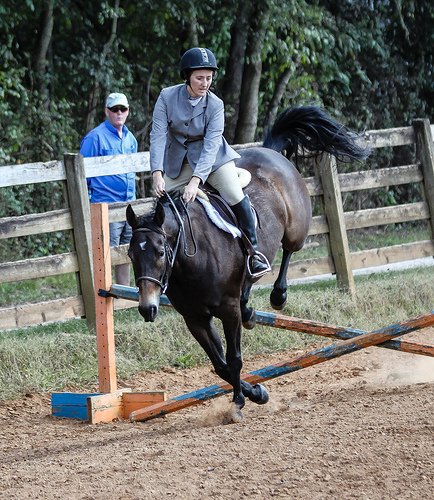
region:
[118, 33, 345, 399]
A woman riding a black horse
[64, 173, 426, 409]
Horse jumping fences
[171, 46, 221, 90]
A black riders hat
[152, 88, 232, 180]
A woman wearing a light gray jacket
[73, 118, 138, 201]
A blue long sleeved shirt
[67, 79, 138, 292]
A man standing on other side of fence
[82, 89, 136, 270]
A man wearing a hat and sunglasses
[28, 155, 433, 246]
A long wooden fence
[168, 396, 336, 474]
A dirt riding path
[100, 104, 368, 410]
A dark brown horse with a black mane and tail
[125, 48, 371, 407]
a woman at dressage competition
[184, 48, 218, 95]
a hat on the competitor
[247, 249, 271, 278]
metal stirrup on a riding saddle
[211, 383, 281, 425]
hooves kicking up dirt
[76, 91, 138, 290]
a man watching the competition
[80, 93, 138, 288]
a man wearing dark glasses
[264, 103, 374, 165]
the tail of the horse flying upward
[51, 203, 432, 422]
a jump for the horse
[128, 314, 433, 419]
a bar with blue and brown stripes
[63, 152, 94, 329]
a wooden fence post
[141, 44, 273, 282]
woman in gray riding brown horse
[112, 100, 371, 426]
Brown horse with white star on head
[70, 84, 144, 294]
man watching woman on horse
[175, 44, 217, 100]
helmet on the womans head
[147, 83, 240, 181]
gray riding jacket the woman has on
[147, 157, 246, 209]
white pants the woman is wearing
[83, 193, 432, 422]
hurdle the horse tried to jump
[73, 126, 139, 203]
mans blue shirt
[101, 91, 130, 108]
hat the man is wearing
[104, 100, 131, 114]
sunglasses the man is wearing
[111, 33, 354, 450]
A woman riding a horse.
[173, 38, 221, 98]
A woman wearing a safety helmet.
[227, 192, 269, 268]
A black riding boot on the left leg.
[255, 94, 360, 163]
A horse's black tail.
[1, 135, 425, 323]
A wooden fence behind the horse.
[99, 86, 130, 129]
A man wearing sunglasses.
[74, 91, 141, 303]
A man standing behind the fence.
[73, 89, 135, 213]
A man wearing a blue shirt.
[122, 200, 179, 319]
The horse's head.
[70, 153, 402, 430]
A horse jumping an obstacle.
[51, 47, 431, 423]
Woman on a horse jumping over a metal bar.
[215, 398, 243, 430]
Dirt flying up where the front hoof meets the dirt.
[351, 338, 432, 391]
Dust kicked up on the ground behind the horse.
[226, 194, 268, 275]
The woman is wearing black horse riding boots.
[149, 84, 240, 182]
The woman is wearing a blue riding jacket.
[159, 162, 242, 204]
The woman is wearing white riding pants.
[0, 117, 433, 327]
A wooden fence behind the horse and rider.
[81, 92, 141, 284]
A man is standing near the fence watching the rider.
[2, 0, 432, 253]
Trees behind the man.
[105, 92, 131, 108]
The man is wearing a white cap on his head.